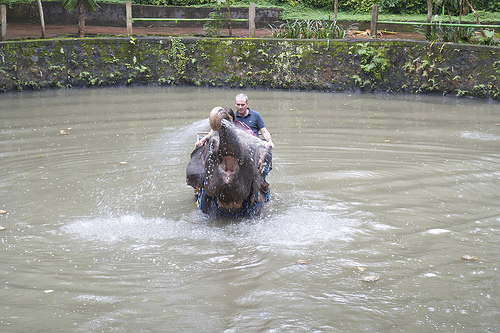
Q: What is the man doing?
A: Riding the elephant.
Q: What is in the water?
A: Elephant.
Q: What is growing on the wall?
A: Green plants.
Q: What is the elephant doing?
A: Blowing water.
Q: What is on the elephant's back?
A: Two people.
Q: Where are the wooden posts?
A: Above the wall.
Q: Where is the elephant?
A: Middle of the pond.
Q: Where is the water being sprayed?
A: From trunk of elephant.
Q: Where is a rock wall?
A: Back side of pond.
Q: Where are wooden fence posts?
A: Just behind the rock wall.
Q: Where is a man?
A: On the back of the elephant.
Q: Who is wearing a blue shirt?
A: Man on elephant.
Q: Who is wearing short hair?
A: Man on the elephant.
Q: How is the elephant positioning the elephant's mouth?
A: Open.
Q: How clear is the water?
A: Water is murky.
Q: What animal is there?
A: Elephant.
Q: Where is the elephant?
A: In the water.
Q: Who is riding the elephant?
A: The man.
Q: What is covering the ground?
A: Water.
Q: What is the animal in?
A: A pond.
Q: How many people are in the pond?
A: One.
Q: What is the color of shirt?
A: Blue.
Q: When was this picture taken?
A: Daytime.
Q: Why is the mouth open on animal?
A: Squirting water.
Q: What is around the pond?
A: Posts.